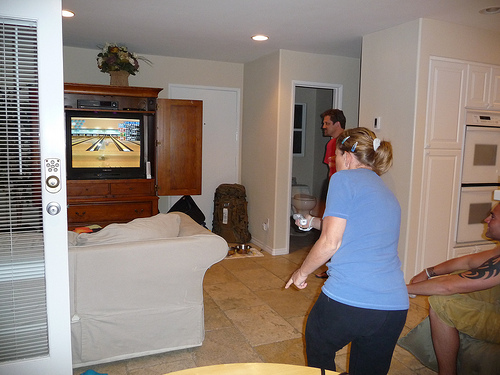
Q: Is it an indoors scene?
A: Yes, it is indoors.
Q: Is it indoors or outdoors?
A: It is indoors.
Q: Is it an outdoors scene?
A: No, it is indoors.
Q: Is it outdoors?
A: No, it is indoors.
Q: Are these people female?
A: No, they are both male and female.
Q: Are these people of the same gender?
A: No, they are both male and female.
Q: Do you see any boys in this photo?
A: No, there are no boys.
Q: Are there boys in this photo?
A: No, there are no boys.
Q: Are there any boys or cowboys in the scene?
A: No, there are no boys or cowboys.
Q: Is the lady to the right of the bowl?
A: Yes, the lady is to the right of the bowl.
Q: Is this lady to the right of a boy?
A: No, the lady is to the right of the bowl.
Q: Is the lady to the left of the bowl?
A: No, the lady is to the right of the bowl.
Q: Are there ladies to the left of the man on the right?
A: Yes, there is a lady to the left of the man.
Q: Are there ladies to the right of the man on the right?
A: No, the lady is to the left of the man.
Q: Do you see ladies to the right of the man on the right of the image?
A: No, the lady is to the left of the man.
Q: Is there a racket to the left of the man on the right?
A: No, there is a lady to the left of the man.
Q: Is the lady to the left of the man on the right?
A: Yes, the lady is to the left of the man.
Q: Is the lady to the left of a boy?
A: No, the lady is to the left of the man.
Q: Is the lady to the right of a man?
A: No, the lady is to the left of a man.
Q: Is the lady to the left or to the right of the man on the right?
A: The lady is to the left of the man.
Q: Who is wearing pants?
A: The lady is wearing pants.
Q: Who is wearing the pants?
A: The lady is wearing pants.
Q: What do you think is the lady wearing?
A: The lady is wearing trousers.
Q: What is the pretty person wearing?
A: The lady is wearing trousers.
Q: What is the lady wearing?
A: The lady is wearing trousers.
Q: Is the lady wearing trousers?
A: Yes, the lady is wearing trousers.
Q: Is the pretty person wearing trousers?
A: Yes, the lady is wearing trousers.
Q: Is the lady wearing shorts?
A: No, the lady is wearing trousers.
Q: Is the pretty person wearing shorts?
A: No, the lady is wearing trousers.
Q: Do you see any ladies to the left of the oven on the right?
A: Yes, there is a lady to the left of the oven.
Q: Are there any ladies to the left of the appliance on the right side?
A: Yes, there is a lady to the left of the oven.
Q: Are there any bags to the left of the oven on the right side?
A: No, there is a lady to the left of the oven.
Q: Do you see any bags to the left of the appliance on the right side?
A: No, there is a lady to the left of the oven.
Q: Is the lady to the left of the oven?
A: Yes, the lady is to the left of the oven.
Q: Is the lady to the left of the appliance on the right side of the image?
A: Yes, the lady is to the left of the oven.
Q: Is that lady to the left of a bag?
A: No, the lady is to the left of the oven.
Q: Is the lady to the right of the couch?
A: Yes, the lady is to the right of the couch.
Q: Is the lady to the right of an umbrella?
A: No, the lady is to the right of the couch.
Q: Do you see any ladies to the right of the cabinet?
A: Yes, there is a lady to the right of the cabinet.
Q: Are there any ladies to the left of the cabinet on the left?
A: No, the lady is to the right of the cabinet.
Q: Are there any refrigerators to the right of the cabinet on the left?
A: No, there is a lady to the right of the cabinet.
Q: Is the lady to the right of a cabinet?
A: Yes, the lady is to the right of a cabinet.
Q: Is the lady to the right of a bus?
A: No, the lady is to the right of a cabinet.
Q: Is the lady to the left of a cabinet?
A: No, the lady is to the right of a cabinet.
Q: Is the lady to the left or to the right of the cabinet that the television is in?
A: The lady is to the right of the cabinet.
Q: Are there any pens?
A: No, there are no pens.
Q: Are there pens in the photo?
A: No, there are no pens.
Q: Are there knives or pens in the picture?
A: No, there are no pens or knives.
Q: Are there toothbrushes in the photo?
A: No, there are no toothbrushes.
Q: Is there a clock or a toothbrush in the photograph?
A: No, there are no toothbrushes or clocks.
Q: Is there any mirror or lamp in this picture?
A: No, there are no lamps or mirrors.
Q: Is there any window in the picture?
A: Yes, there is a window.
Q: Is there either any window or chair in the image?
A: Yes, there is a window.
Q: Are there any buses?
A: No, there are no buses.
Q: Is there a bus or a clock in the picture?
A: No, there are no buses or clocks.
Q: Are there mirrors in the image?
A: No, there are no mirrors.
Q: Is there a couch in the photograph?
A: Yes, there is a couch.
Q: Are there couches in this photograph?
A: Yes, there is a couch.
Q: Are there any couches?
A: Yes, there is a couch.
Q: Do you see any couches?
A: Yes, there is a couch.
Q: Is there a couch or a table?
A: Yes, there is a couch.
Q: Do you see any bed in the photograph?
A: No, there are no beds.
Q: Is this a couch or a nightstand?
A: This is a couch.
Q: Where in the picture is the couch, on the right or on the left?
A: The couch is on the left of the image.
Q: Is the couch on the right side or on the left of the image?
A: The couch is on the left of the image.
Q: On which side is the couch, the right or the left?
A: The couch is on the left of the image.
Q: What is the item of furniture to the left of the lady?
A: The piece of furniture is a couch.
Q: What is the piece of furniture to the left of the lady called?
A: The piece of furniture is a couch.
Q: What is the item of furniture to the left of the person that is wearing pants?
A: The piece of furniture is a couch.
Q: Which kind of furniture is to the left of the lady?
A: The piece of furniture is a couch.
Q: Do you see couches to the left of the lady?
A: Yes, there is a couch to the left of the lady.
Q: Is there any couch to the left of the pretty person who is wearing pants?
A: Yes, there is a couch to the left of the lady.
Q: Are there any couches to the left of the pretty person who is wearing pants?
A: Yes, there is a couch to the left of the lady.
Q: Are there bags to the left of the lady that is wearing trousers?
A: No, there is a couch to the left of the lady.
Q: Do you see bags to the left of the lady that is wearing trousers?
A: No, there is a couch to the left of the lady.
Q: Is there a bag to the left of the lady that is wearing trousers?
A: No, there is a couch to the left of the lady.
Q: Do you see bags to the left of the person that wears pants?
A: No, there is a couch to the left of the lady.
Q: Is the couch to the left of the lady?
A: Yes, the couch is to the left of the lady.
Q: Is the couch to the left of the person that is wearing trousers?
A: Yes, the couch is to the left of the lady.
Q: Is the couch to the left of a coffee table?
A: No, the couch is to the left of the lady.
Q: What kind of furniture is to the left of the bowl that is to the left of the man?
A: The piece of furniture is a couch.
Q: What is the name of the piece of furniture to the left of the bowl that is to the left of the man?
A: The piece of furniture is a couch.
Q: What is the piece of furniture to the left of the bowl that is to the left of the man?
A: The piece of furniture is a couch.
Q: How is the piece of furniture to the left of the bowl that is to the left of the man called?
A: The piece of furniture is a couch.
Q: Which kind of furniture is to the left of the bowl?
A: The piece of furniture is a couch.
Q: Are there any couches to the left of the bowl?
A: Yes, there is a couch to the left of the bowl.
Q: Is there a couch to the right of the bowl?
A: No, the couch is to the left of the bowl.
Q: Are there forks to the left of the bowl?
A: No, there is a couch to the left of the bowl.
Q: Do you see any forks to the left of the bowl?
A: No, there is a couch to the left of the bowl.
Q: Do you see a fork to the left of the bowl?
A: No, there is a couch to the left of the bowl.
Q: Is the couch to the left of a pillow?
A: No, the couch is to the left of the bowl.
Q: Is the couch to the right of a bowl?
A: No, the couch is to the left of a bowl.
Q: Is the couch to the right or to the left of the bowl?
A: The couch is to the left of the bowl.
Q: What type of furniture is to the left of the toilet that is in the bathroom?
A: The piece of furniture is a couch.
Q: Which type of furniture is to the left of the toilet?
A: The piece of furniture is a couch.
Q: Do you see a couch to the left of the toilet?
A: Yes, there is a couch to the left of the toilet.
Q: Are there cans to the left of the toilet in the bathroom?
A: No, there is a couch to the left of the toilet.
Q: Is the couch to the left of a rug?
A: No, the couch is to the left of a toilet.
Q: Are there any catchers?
A: No, there are no catchers.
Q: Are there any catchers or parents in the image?
A: No, there are no catchers or parents.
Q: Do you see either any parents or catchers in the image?
A: No, there are no catchers or parents.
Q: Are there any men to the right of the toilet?
A: Yes, there is a man to the right of the toilet.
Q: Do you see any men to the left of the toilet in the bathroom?
A: No, the man is to the right of the toilet.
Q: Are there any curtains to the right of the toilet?
A: No, there is a man to the right of the toilet.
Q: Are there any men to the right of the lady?
A: Yes, there is a man to the right of the lady.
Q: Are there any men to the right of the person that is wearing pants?
A: Yes, there is a man to the right of the lady.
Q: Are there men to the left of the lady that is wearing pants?
A: No, the man is to the right of the lady.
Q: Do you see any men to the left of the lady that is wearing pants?
A: No, the man is to the right of the lady.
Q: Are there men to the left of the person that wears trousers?
A: No, the man is to the right of the lady.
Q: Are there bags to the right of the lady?
A: No, there is a man to the right of the lady.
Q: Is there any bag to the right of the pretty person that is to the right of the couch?
A: No, there is a man to the right of the lady.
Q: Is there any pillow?
A: No, there are no pillows.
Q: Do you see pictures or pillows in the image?
A: No, there are no pillows or pictures.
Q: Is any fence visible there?
A: No, there are no fences.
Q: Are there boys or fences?
A: No, there are no fences or boys.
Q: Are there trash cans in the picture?
A: No, there are no trash cans.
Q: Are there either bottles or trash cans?
A: No, there are no trash cans or bottles.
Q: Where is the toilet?
A: The toilet is in the bathroom.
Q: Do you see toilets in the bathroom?
A: Yes, there is a toilet in the bathroom.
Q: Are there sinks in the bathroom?
A: No, there is a toilet in the bathroom.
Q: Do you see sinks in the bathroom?
A: No, there is a toilet in the bathroom.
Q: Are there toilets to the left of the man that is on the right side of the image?
A: Yes, there is a toilet to the left of the man.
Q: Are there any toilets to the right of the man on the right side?
A: No, the toilet is to the left of the man.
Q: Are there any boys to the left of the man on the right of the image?
A: No, there is a toilet to the left of the man.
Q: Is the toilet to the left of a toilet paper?
A: No, the toilet is to the left of the man.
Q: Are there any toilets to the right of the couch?
A: Yes, there is a toilet to the right of the couch.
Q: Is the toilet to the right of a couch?
A: Yes, the toilet is to the right of a couch.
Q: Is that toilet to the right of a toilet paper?
A: No, the toilet is to the right of a couch.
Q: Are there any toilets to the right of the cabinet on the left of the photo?
A: Yes, there is a toilet to the right of the cabinet.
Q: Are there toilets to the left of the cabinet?
A: No, the toilet is to the right of the cabinet.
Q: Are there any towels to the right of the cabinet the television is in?
A: No, there is a toilet to the right of the cabinet.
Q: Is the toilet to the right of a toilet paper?
A: No, the toilet is to the right of the cabinet.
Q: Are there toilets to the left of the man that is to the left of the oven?
A: Yes, there is a toilet to the left of the man.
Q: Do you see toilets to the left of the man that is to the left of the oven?
A: Yes, there is a toilet to the left of the man.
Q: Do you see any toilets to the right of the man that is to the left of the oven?
A: No, the toilet is to the left of the man.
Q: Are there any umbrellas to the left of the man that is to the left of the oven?
A: No, there is a toilet to the left of the man.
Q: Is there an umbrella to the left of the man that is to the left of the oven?
A: No, there is a toilet to the left of the man.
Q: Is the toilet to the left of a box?
A: No, the toilet is to the left of the man.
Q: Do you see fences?
A: No, there are no fences.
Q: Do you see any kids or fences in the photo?
A: No, there are no fences or kids.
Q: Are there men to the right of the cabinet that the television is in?
A: Yes, there is a man to the right of the cabinet.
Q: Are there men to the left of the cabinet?
A: No, the man is to the right of the cabinet.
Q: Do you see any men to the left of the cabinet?
A: No, the man is to the right of the cabinet.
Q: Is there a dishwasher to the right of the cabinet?
A: No, there is a man to the right of the cabinet.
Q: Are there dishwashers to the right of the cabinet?
A: No, there is a man to the right of the cabinet.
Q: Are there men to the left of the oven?
A: Yes, there is a man to the left of the oven.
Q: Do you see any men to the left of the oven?
A: Yes, there is a man to the left of the oven.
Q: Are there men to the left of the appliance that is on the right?
A: Yes, there is a man to the left of the oven.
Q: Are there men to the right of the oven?
A: No, the man is to the left of the oven.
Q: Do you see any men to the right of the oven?
A: No, the man is to the left of the oven.